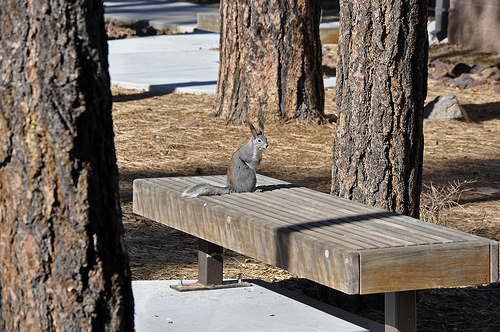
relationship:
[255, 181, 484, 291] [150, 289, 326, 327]
bench on slab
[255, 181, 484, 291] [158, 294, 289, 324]
bench on cement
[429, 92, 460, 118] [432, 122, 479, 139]
rock on ground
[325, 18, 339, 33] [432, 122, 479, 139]
snow on ground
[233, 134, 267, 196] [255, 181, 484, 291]
squirrel stiiting on bench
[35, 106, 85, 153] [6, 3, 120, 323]
bark of tree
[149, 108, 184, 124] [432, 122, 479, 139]
patch of ground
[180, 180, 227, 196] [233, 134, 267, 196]
tail of squirrel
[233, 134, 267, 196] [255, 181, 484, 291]
rabbit on a bench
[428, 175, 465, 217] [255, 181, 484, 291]
shrub ot right of bench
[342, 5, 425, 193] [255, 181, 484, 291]
trunk behind bench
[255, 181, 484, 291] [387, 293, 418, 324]
bench with leg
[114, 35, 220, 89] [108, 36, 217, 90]
cement in background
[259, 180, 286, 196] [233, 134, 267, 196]
shadow cast by rabbit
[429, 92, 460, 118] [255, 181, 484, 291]
rock next to bench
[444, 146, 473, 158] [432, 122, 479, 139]
straw on ground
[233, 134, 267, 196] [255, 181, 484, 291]
squirrel on a bench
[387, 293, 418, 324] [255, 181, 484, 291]
support under bench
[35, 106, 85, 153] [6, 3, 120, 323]
bark on tree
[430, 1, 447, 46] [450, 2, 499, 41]
pipe attached to building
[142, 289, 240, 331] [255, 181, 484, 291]
pad under bench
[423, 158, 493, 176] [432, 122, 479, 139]
shadow on ground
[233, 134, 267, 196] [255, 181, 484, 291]
squirrel on bench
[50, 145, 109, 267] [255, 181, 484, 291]
trunk on side of bench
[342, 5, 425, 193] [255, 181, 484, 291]
trunk on side of bench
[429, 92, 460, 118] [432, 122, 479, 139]
stone on ground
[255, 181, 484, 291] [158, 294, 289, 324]
bench on platform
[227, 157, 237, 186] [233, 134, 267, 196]
spot on back of squirrel